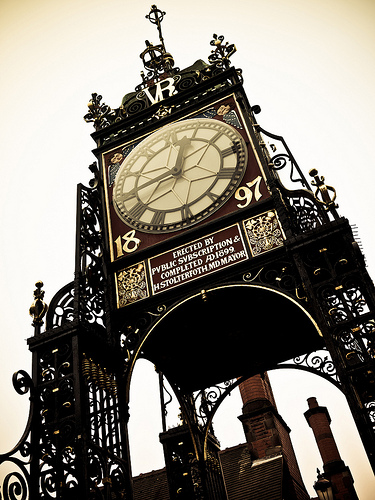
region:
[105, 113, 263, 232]
Large clock in the front of the tower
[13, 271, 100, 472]
Metal scrolling on the side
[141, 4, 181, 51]
Peak on the tower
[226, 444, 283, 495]
Shingled roof on the church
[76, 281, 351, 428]
Metal half circle arch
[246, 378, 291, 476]
Brick steeple in the background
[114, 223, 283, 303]
Sign saying who it was erected by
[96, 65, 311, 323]
The clock is at the very top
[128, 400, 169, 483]
The sky is cloudy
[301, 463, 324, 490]
Street lamp beside the church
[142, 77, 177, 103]
Silver initials on top of clock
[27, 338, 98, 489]
Decorative scrolling on side of clock tower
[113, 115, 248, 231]
Gold clock face with grayish brown hands and numbers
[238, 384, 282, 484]
Tall brick building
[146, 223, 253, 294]
Commemorative plaque mounted below clock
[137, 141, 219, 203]
Decorative star in middle of clock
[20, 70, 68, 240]
White cloudless sky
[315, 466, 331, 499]
Top of street light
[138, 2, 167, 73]
Decorative spheres on top of clock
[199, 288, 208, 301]
Gold knob in center of clock tower arch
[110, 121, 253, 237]
the large circle clock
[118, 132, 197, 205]
the hands on the clock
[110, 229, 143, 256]
the 18 on the clock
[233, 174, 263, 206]
the 97 on the clock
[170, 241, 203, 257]
the word ERECTED on the sign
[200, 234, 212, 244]
the word BY on the sign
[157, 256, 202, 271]
the word COMPLETED on the sign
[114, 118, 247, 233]
the roman numerals on the clock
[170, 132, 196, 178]
the hour hand on the clock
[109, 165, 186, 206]
the minutes hand on the clock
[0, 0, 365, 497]
a wrought iron clock tower built in 1897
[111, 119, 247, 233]
the clock face is white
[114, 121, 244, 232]
the clock hands and roman numerals are black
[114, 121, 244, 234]
a black trim is around the face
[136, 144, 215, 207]
a star relief is on the face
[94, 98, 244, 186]
the clock has angels on the corners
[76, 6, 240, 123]
iron filigree is on top of the tower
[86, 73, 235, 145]
parapets are above the clock face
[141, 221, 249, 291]
a plaque is below the clock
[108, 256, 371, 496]
iron filigree arches are below the clock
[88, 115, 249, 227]
large gold clock face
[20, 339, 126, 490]
black metal clock framing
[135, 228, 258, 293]
white writing below clock face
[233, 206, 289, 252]
design below clock face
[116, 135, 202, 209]
gold metal clock hands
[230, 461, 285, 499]
brown shingles on building roof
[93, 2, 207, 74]
metal design on top of clock tower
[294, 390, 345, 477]
brown stone chimney on building roof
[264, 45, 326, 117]
hazy sky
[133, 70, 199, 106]
golden lettering above clock face